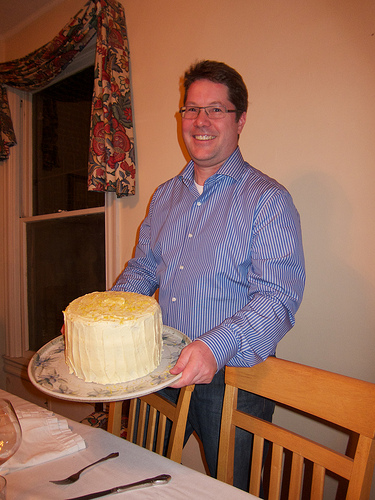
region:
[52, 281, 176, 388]
A CAKE WITH WHITE FROSTING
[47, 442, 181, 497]
A FORK AND BUTTER KNIFE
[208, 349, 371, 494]
THE BACK OF A WOODEN CHAIR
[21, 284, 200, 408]
A CHINA PLATTER WITH A CAKE ON IT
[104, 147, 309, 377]
A MAN'S BLUE DRESS SHIRT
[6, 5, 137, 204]
A FLOWERED WINDOW CURTAIN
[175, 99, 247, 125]
A PAIR OF GLASSES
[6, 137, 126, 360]
A WINDOW TO THE LEFT OF THE MAN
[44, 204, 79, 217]
THE LOCK ON TOP OF THE WINDOW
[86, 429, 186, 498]
A WHITE TABLE CLOTH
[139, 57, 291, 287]
A smiling guy with brown hair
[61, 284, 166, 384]
Tall homemade cake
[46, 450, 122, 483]
Fork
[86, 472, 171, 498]
Knife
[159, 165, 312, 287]
Shirt with tight blue and white stripes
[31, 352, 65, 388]
Floral design on large platter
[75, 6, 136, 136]
Busy floral patterned window treatment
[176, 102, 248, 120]
Glasses being worn by happy man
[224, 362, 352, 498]
Wooden chair back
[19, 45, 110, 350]
Large window next to man with cake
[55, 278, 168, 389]
Cream colored cake on platter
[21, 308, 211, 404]
Platter with cake on it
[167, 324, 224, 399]
Man's left hand holding cake platter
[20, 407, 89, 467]
Napkins on table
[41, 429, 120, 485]
Silver fork on table top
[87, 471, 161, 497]
Silver knife on table top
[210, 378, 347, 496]
Chair back with openings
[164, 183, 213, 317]
Buttons on blue and white shirt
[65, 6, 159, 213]
Red, beige and green curtain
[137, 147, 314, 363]
Blue and white dressed shirt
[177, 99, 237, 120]
Man has to wear eyeglasses to see well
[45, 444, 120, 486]
Silver fork on the white tablecloth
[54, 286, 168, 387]
Round multi-layer cake for a celebration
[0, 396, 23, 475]
Top portion of a wine glass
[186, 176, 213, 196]
Wearing a white t-shirt under his blue striped shirt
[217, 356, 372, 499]
Light stained solid wood dining chairs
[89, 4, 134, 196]
Right side of floral and paisley patterned valance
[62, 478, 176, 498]
A silver butter knife laying on table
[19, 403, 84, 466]
Stack of folded linen napkins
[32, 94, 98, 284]
Bare window panes at night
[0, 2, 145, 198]
Red, white and green drapes hanging over window.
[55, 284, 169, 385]
Yellow cake on plate.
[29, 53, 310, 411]
Man in blue shirt holding cake.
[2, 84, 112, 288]
Window with darkness outside.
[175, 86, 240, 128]
Dark-rimmed glasses on man's face.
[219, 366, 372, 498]
Wooden chair in front of table.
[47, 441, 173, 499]
Fork and Knife silverware sits on table.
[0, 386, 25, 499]
Wine glass sits on table.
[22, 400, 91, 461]
White napkin on table.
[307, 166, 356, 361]
Man's shadow on white wall.